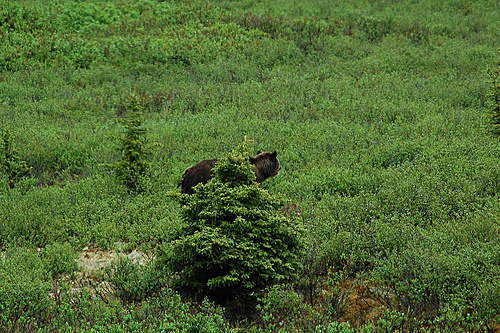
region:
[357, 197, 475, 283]
the plants are green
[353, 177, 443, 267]
the plants are green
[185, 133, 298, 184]
this is a bear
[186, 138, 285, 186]
the bear is black in color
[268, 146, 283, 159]
the ear is big in siz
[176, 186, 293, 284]
this is a tree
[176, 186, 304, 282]
the tree is small is size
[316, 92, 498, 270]
the leaves are green in color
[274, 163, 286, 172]
the mouth is open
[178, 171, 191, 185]
the tail is short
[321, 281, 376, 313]
the branches are brown in color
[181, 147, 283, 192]
the bear is big in size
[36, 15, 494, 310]
a natural green landscape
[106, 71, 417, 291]
a bear in it's element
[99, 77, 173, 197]
a young evergreen tree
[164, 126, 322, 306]
a short and wide tree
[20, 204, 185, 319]
a patch of dirt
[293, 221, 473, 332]
a few bare branches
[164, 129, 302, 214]
a wild brown bear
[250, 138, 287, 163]
two small, rounded ears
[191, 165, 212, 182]
thick, brown fur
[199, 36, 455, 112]
a large amount of green plants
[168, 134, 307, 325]
this is a tree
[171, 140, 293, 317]
the tree is green in color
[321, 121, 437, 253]
these are vegetations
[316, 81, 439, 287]
the vegetation are small in size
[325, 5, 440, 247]
the vegetation are green in color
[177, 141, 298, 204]
this is a bear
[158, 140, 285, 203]
the bear is dark brown in color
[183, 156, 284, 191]
the bear's fur is rugged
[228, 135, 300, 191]
the bear is looking at something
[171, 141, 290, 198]
bear is large and black